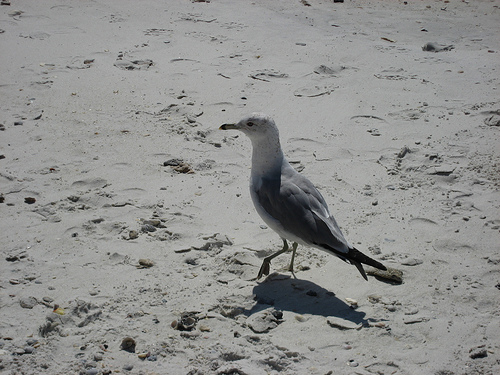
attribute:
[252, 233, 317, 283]
feet — seagull's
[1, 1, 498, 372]
sand — gray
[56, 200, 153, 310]
sand — gray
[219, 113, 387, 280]
seagull — stands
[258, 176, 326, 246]
feathers — gray, bird's feather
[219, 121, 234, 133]
tip — black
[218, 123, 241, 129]
beak — seagull's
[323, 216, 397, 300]
tail feather — seagull's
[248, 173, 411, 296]
wing — gray